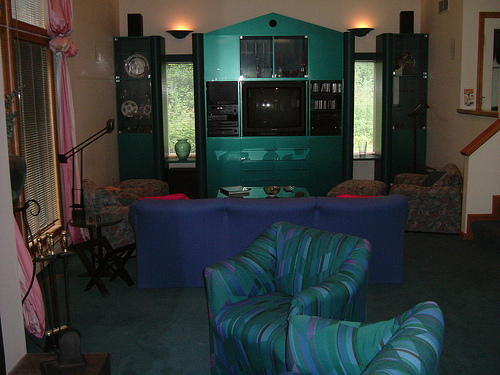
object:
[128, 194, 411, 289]
couch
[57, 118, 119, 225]
mic stand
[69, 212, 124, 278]
table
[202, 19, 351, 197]
entertainment center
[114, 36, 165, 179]
cabinet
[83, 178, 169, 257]
chairs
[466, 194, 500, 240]
staircase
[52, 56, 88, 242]
drapes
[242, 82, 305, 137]
tv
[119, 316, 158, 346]
floor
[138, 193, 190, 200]
pillow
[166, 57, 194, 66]
trim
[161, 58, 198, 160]
window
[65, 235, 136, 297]
seat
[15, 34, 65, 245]
blinds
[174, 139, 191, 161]
vase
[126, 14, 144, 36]
speaker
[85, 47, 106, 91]
wall